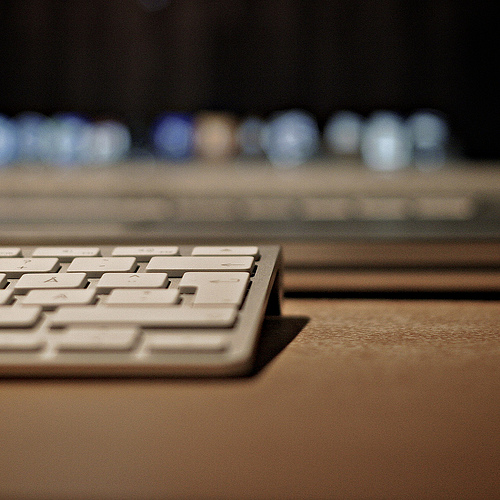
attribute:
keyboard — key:
[1, 226, 306, 387]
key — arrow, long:
[142, 253, 255, 271]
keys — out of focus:
[1, 303, 240, 357]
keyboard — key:
[0, 243, 287, 379]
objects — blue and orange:
[8, 111, 444, 173]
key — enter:
[184, 267, 248, 309]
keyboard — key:
[30, 237, 305, 384]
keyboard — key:
[45, 218, 292, 366]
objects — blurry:
[284, 86, 441, 179]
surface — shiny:
[300, 284, 470, 430]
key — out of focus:
[181, 264, 251, 307]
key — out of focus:
[107, 284, 181, 307]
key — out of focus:
[96, 268, 168, 293]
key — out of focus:
[16, 288, 97, 308]